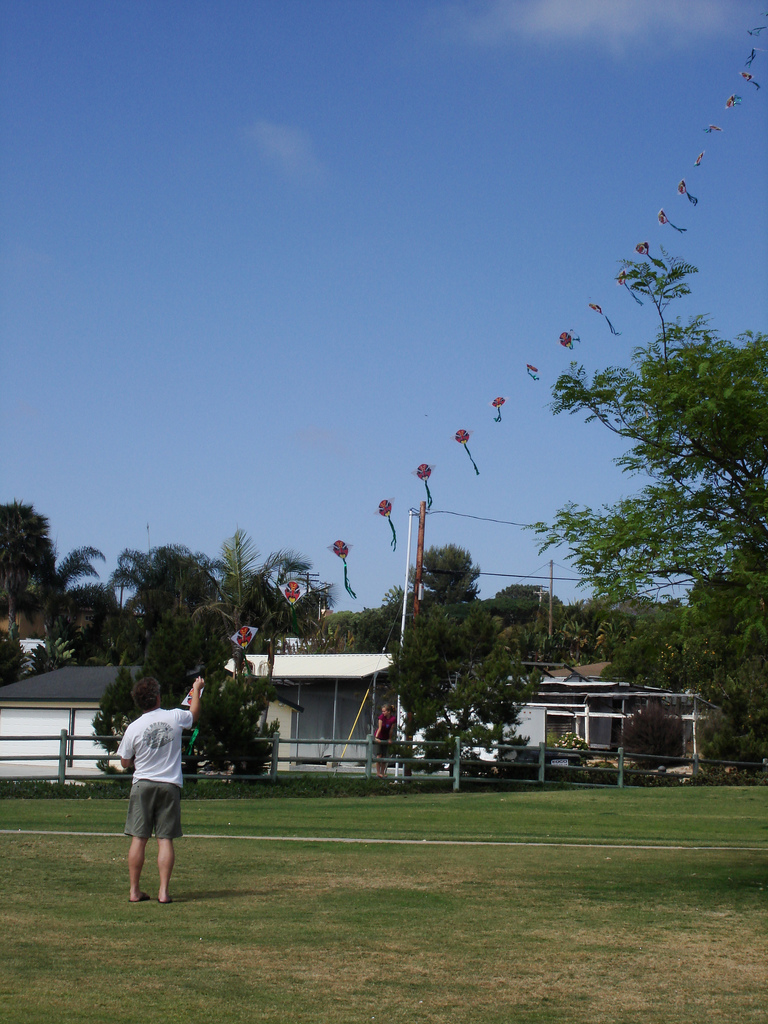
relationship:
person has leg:
[81, 661, 224, 924] [154, 824, 183, 901]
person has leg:
[81, 661, 224, 924] [119, 802, 149, 899]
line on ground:
[3, 816, 764, 862] [1, 798, 766, 1014]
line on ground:
[13, 823, 767, 871] [1, 799, 765, 1021]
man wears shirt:
[103, 675, 213, 914] [106, 701, 210, 788]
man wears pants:
[99, 664, 212, 908] [123, 772, 182, 842]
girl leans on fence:
[366, 698, 405, 774] [8, 721, 753, 813]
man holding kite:
[96, 673, 218, 907] [206, 366, 543, 692]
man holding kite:
[96, 673, 218, 907] [585, 293, 628, 343]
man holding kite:
[96, 673, 218, 907] [669, 175, 716, 209]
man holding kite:
[96, 673, 218, 907] [321, 530, 365, 604]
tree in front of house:
[202, 663, 279, 783] [4, 643, 403, 785]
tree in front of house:
[1, 493, 68, 687] [4, 643, 403, 785]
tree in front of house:
[405, 536, 484, 668] [4, 643, 403, 785]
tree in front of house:
[545, 244, 736, 692] [4, 643, 403, 785]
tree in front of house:
[385, 600, 534, 794] [459, 653, 734, 781]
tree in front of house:
[78, 664, 159, 772] [4, 643, 403, 785]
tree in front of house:
[78, 664, 159, 772] [439, 654, 736, 771]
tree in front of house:
[385, 600, 534, 794] [4, 643, 403, 785]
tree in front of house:
[538, 240, 740, 755] [4, 643, 403, 785]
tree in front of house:
[1, 485, 61, 686] [4, 643, 403, 785]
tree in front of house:
[384, 536, 483, 618] [4, 643, 403, 785]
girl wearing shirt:
[366, 698, 405, 773] [373, 714, 394, 731]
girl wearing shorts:
[366, 698, 405, 774] [373, 738, 387, 755]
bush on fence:
[617, 695, 679, 776] [7, 733, 744, 788]